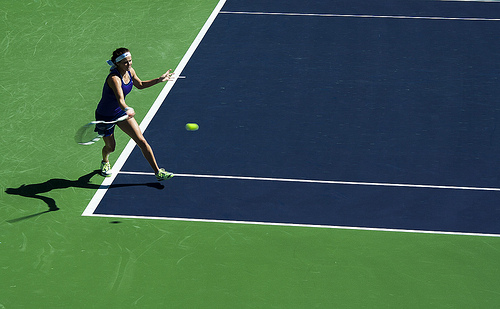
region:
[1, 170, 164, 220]
a shadow on the ground of a tennis player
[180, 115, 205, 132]
a tennis ball in the air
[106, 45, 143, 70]
the head of a woman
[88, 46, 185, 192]
a woman in blue playing tennise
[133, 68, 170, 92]
the arm of a woman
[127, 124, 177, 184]
the leg of a woman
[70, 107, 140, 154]
a hand holding a tennis racket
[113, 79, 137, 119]
the arm of a woman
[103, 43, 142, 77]
a woman wearing a white head band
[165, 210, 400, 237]
the white line of tennis court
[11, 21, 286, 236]
a woman tennis player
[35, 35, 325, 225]
a player hitting a tennis ball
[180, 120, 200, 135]
a yellow tennis ball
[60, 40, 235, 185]
a player hitting a forehand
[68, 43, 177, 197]
a woman wearing a tennis outfit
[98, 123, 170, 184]
the legs of a woman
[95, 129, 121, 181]
the leg of a woman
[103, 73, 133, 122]
the arm of a woman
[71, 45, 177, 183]
A tennis player trying to hit a ball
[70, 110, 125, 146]
a white tennis racket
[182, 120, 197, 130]
a tennis ball in the air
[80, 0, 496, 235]
A blue tennis court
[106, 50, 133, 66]
A white headband on a tennis player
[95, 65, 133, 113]
a blue tank top on a tennis player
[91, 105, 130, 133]
A blue pair of shorts on a tennis player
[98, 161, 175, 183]
A pair of shoes on a tennis player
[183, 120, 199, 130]
a tennis ball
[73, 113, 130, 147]
a tennis racket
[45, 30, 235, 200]
woman wearing a head band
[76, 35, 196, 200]
woman wearing a dress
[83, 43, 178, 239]
woman wearing green shoes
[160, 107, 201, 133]
green ball in the air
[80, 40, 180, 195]
woman holding a racket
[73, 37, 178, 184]
woman hitting a ball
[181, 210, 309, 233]
line on a court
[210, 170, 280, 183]
line on a court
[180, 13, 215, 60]
line on a court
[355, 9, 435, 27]
line on a court